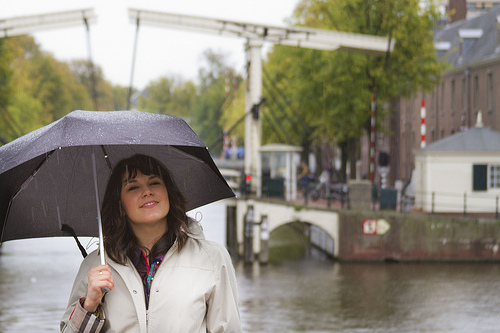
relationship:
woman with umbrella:
[95, 161, 183, 256] [1, 94, 239, 250]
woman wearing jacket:
[95, 161, 183, 256] [75, 246, 234, 329]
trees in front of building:
[263, 20, 398, 193] [381, 37, 498, 131]